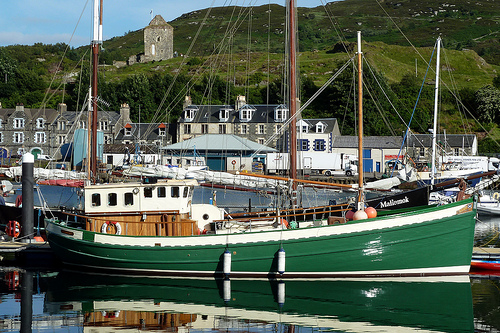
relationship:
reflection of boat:
[10, 292, 439, 331] [47, 219, 476, 282]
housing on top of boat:
[78, 208, 206, 237] [47, 219, 476, 282]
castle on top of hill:
[130, 18, 173, 60] [100, 34, 268, 98]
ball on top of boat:
[361, 200, 382, 229] [47, 219, 476, 282]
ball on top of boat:
[342, 195, 367, 224] [47, 219, 476, 282]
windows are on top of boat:
[86, 187, 137, 214] [35, 180, 485, 320]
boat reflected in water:
[47, 219, 476, 282] [40, 277, 486, 331]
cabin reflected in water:
[79, 160, 227, 244] [40, 277, 486, 331]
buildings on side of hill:
[143, 19, 173, 63] [100, 34, 268, 98]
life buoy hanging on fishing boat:
[99, 218, 121, 237] [37, 163, 478, 290]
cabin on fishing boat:
[79, 160, 227, 244] [37, 179, 469, 290]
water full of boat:
[40, 277, 486, 331] [47, 219, 476, 282]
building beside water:
[7, 110, 472, 155] [40, 277, 486, 331]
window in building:
[183, 121, 192, 135] [181, 101, 291, 153]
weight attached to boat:
[220, 249, 235, 279] [47, 219, 476, 282]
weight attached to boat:
[272, 242, 291, 282] [47, 219, 476, 282]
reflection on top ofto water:
[10, 276, 469, 331] [40, 277, 486, 331]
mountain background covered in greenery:
[4, 0, 490, 138] [182, 25, 437, 99]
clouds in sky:
[3, 29, 82, 46] [3, 0, 189, 50]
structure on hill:
[139, 11, 183, 63] [100, 34, 268, 98]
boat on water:
[47, 219, 476, 282] [40, 277, 486, 331]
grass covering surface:
[200, 23, 271, 93] [110, 12, 492, 141]